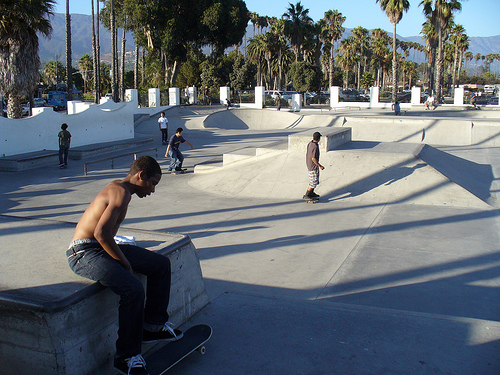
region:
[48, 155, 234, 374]
Teenager sitting on street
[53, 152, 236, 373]
Teenager without a top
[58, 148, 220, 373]
Teenager with a skateboard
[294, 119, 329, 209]
Men with a cap skateboarding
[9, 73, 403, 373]
Five boys skateboarding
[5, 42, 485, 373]
Five boys with skateboards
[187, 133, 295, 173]
Ladders of skateboard field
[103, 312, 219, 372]
Black skateboard on concrete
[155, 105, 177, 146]
Man with white shirt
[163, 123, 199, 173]
Teenager with bending knees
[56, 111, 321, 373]
kids in a skate park.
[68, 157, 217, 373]
A shirtless black boy getting ready to skate.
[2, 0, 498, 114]
Lots of trees in the background.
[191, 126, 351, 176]
concrete stairs in a skating park.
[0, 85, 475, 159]
white concrete plinths in the background surrounding the skate park.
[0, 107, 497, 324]
A skate park with several ramps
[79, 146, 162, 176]
A metal rail in the skate park.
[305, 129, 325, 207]
a boy wearing a brown shirt skating.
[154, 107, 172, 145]
A boy wearing a white shirt on a skateboard.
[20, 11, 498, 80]
Mountainous hills in the distance.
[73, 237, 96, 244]
top of boy's gray underwear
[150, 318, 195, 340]
black sneakers with white laces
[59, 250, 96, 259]
boy's thin gray belt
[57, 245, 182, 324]
boy's blue jeans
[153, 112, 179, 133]
man wearing a white tee shirt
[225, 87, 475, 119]
rows of white columns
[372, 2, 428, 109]
tall green palm tree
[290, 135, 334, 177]
man wearing brown shirt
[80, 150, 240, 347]
boy sitting on pavement with his feet on a skateboard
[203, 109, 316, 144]
large indent in pavement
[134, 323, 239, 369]
a black skateboard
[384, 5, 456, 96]
palm trees in the backdrop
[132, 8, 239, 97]
green leaved trees in the backdrop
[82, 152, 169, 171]
a skating rail in the park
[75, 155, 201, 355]
a skater resting on a block of cement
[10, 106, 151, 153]
white wall of the skatepark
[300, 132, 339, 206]
a man about to ride up a block of concrete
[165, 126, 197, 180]
a man preparing to jump his skateboard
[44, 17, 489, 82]
mountains in the backdrop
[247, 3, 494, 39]
blue sky in the backdrop